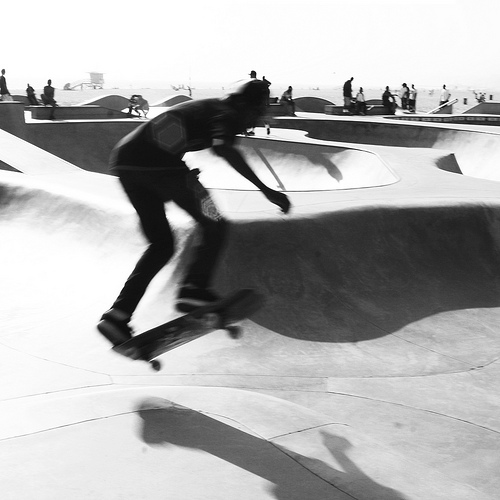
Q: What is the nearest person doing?
A: Skateboarding.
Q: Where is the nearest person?
A: In the air.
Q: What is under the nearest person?
A: A skateboard.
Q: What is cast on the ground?
A: Shadows.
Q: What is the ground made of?
A: Cement.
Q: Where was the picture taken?
A: At a skatepark.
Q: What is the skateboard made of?
A: Wood.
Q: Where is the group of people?
A: On the far end of the skate park.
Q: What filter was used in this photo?
A: Black and white.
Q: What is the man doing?
A: Skateboarding.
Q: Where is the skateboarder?
A: On the ramp.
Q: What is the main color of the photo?
A: Black and white.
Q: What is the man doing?
A: PErforming a trick.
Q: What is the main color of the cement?
A: Gray.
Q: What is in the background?
A: Beach.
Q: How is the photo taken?
A: Black and white.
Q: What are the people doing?
A: Enjoying a skate park.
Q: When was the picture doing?
A: During the day.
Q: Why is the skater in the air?
A: He is jumping.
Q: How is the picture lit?
A: Naturally.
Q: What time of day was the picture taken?
A: Afternoon.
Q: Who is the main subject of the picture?
A: A skater.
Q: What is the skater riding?
A: A skateboard.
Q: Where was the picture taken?
A: At a skateboard park.